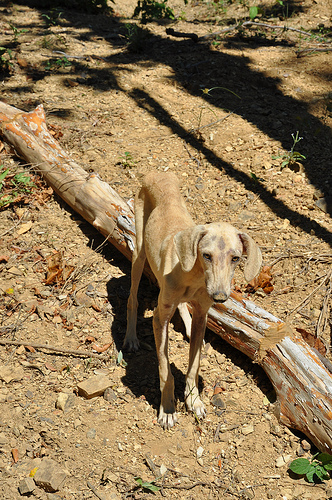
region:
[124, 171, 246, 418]
One dog is standing.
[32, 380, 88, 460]
Ground is brown color.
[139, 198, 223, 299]
Dog is brown color.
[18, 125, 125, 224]
Log is brown color.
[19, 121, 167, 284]
Log lies behind the dog in ground.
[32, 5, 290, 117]
Shadow falls on ground.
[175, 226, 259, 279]
Dog has two brown ears.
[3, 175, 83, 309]
Dried leaves lie on ground.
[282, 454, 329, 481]
Leaves are green color.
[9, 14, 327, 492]
Day time picture.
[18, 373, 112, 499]
odd shaped blocks of wood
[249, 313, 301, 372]
log sawed in two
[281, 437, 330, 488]
brad leafed green weed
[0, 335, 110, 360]
a random stick lies on the ground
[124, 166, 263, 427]
a starving dog stands alone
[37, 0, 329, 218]
shadows lay across the ground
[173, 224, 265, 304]
dirt marks stain dog's face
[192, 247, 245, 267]
the sad eyes of a dog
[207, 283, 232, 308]
adry nose indicates a sick animal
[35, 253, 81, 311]
dead and dry leaves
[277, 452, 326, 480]
small green leaf on ground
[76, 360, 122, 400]
small white brick on ground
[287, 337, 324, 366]
orange color on rotting wood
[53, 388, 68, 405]
small white rock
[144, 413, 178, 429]
black nails on dog's foot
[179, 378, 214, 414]
black lines on dog's foot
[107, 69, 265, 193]
shadow cast of a tall tree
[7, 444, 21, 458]
tiny gold leaf on ground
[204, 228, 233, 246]
small gray spot on dog's face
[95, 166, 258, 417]
large thin dog on ground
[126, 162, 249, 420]
very thing brown dog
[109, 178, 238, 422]
skinny dog standing on dirt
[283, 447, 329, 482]
small green leaves beside log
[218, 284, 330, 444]
weathered piece of wood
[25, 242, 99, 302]
brown leaves on dirty groung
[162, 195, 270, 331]
brown dog with black spot in middle of head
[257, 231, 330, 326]
small brown twigs on ground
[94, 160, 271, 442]
dog standing in front of log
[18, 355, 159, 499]
rocks on ground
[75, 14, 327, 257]
shadows on ground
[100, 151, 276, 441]
emaciated dog in the dirt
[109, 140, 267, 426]
yellow dog that is too skinny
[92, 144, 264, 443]
skinny dirty yellow dog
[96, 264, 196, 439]
shadow of dog on ground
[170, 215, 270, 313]
dirty scabbed head of a dog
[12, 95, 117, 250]
dead tree trunk on the ground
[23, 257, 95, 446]
wood chips and dead leaves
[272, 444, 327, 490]
one touch of green amid brown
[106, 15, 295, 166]
shadow of tree on ground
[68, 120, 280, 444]
skinny dog in a sunny forest